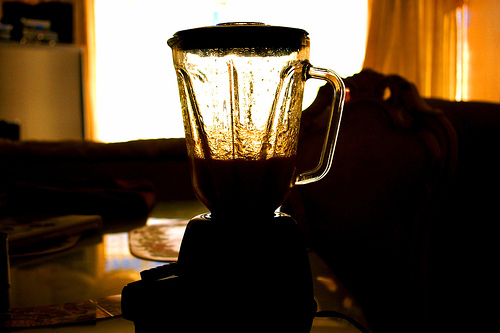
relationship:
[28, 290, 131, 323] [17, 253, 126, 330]
paperwork sitting on counter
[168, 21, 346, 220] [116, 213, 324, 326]
pitcher on stand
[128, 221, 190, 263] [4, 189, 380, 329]
mat on table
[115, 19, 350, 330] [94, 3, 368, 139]
blender against window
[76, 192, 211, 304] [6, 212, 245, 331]
napkins on table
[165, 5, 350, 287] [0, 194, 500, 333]
kitchen appliance on counter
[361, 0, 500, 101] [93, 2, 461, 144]
curtain over sunny window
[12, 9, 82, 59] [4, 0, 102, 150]
shelf hanging on wall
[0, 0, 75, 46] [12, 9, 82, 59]
books on shelf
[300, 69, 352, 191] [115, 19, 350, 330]
handle on blender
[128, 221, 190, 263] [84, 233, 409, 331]
mat on table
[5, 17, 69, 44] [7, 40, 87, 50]
things on shelf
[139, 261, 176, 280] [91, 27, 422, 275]
buttons on blender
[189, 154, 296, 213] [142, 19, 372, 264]
liquid in blender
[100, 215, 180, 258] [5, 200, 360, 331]
reflection on table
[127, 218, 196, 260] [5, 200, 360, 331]
stuff on table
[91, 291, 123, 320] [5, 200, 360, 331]
stuff on table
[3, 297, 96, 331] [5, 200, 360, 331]
stuff on table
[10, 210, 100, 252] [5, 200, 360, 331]
stuff on table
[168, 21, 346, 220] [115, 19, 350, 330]
pitcher on blender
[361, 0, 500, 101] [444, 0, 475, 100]
curtain covering window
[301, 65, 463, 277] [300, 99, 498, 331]
man sitting on sofa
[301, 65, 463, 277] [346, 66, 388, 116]
man has head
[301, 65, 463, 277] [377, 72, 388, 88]
man has hand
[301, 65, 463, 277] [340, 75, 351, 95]
man has hand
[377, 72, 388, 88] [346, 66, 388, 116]
hand held to head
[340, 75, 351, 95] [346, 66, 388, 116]
hand held to head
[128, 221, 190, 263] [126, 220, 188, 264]
mat on placemat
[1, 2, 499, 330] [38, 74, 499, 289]
sunlight on counter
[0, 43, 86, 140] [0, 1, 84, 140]
shelf on wall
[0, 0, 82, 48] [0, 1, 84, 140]
shelf on wall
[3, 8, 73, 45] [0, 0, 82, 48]
books on shelf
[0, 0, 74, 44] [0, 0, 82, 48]
cds on shelf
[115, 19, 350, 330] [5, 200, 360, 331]
blender on a table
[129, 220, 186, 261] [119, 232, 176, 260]
part of a mat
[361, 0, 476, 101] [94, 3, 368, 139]
curtain on a window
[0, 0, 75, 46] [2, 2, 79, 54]
books on a shelf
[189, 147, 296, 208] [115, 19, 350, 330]
liquid in a blender